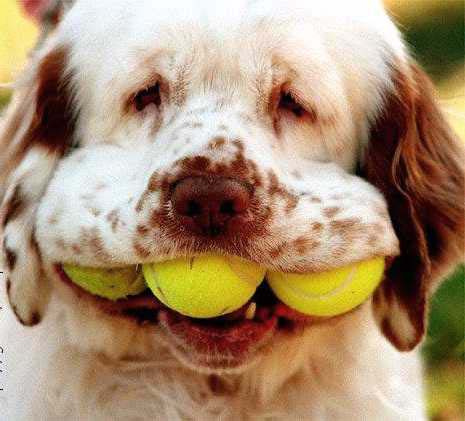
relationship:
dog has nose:
[0, 0, 464, 420] [163, 166, 258, 236]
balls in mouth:
[59, 264, 147, 298] [32, 224, 405, 382]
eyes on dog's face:
[123, 75, 316, 126] [41, 2, 374, 257]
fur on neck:
[238, 358, 307, 401] [93, 356, 340, 418]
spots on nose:
[30, 110, 411, 272] [169, 176, 250, 236]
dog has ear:
[0, 0, 464, 420] [3, 42, 85, 327]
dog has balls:
[0, 0, 464, 420] [60, 247, 385, 316]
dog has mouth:
[0, 0, 464, 420] [39, 249, 398, 375]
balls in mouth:
[265, 253, 387, 317] [39, 249, 398, 375]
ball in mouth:
[141, 251, 266, 318] [39, 249, 398, 375]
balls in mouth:
[59, 264, 147, 298] [39, 249, 398, 375]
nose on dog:
[156, 166, 260, 248] [0, 0, 464, 420]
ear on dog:
[0, 20, 76, 327] [0, 0, 464, 420]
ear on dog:
[359, 56, 463, 351] [0, 0, 464, 420]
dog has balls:
[0, 0, 464, 420] [62, 247, 383, 297]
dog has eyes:
[0, 0, 464, 420] [122, 70, 311, 124]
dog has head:
[48, 26, 427, 390] [1, 1, 464, 394]